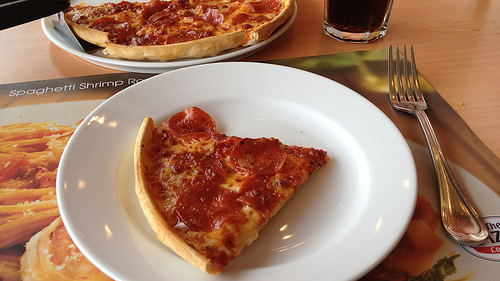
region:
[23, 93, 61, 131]
a place mat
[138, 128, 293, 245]
a peporroni pizza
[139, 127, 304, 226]
a slice of pizza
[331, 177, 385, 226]
a white plate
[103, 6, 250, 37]
slices of pizza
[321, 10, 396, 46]
a glass on the table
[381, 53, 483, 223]
a silver fork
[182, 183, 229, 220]
pepperoni on the pizza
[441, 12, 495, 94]
a table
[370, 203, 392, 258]
reflection of the light on the plate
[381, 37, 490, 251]
a gray metal fork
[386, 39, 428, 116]
the tines of a fork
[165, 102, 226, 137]
a piece of red pepperoni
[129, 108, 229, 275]
the crust of a pizza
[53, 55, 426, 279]
a white plate on the table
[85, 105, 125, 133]
light reflecting on the plate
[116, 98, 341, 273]
pizza on the plate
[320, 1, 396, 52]
a glass on the table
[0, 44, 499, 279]
a place mat on the table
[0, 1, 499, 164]
a brown wooden table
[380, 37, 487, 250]
a fork on a placemat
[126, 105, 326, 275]
a slice of pepperoni pizza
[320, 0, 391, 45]
a glass of soda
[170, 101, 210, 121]
a pepperoni hanging off a piece of pizza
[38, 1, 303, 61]
a pizza on a plate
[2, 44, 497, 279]
a placemat on a table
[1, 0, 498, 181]
a pale wood table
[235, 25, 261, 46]
a cut in the pizza crust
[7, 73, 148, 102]
white words on a placemat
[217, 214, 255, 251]
melted cheese on a pizza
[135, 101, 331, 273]
Pizza on white round plate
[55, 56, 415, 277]
White round plate next to fork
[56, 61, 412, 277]
White round plate on table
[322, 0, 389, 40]
Beverage in front of fork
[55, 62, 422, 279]
White round plate next to white round plate with pizza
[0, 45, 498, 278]
Place mat under white round plate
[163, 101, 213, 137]
Pepperoni slice on pizza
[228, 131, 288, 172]
Pepperoni slice on pizza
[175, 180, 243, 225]
Pepperoni slice on pizza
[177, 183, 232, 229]
Pepperoni slice is red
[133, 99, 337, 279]
a slice of pizza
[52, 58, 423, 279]
a white porcelain plate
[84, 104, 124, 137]
a light shining on the plate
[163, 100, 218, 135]
a red piece of pepperoni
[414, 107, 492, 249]
the handle of a fork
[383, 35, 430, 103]
the tines of a fork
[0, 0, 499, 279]
a brown wooden table